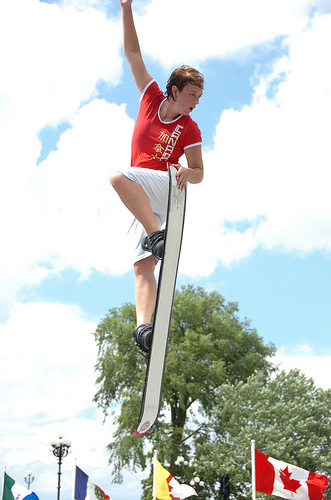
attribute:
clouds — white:
[2, 11, 114, 143]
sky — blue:
[255, 254, 329, 328]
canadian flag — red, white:
[242, 447, 325, 499]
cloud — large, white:
[1, 0, 328, 483]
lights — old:
[46, 432, 70, 471]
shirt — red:
[135, 94, 199, 179]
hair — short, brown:
[164, 65, 203, 99]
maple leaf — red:
[278, 466, 303, 493]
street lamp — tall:
[49, 433, 69, 499]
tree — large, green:
[91, 281, 276, 499]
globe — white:
[64, 441, 70, 447]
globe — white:
[59, 441, 66, 447]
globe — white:
[50, 441, 60, 447]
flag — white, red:
[256, 451, 325, 499]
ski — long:
[132, 161, 186, 437]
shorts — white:
[106, 162, 204, 262]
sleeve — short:
[181, 120, 200, 150]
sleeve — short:
[138, 78, 159, 100]